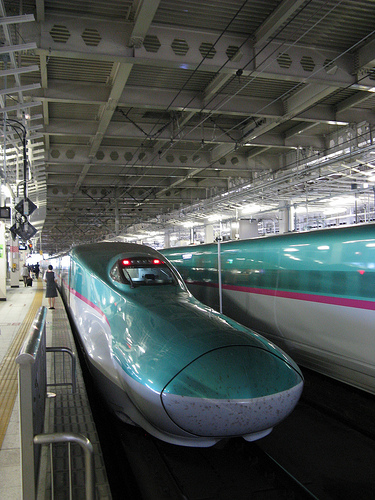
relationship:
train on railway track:
[37, 240, 305, 448] [128, 438, 296, 499]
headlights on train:
[119, 256, 165, 268] [42, 243, 315, 461]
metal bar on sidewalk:
[38, 343, 80, 408] [1, 271, 112, 499]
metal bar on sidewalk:
[30, 431, 96, 498] [1, 271, 112, 499]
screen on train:
[118, 265, 176, 286] [37, 240, 305, 448]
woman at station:
[43, 265, 58, 310] [4, 236, 374, 376]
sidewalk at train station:
[15, 262, 63, 352] [2, 0, 373, 499]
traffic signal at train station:
[25, 241, 33, 250] [2, 0, 373, 499]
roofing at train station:
[23, 16, 350, 195] [2, 0, 373, 499]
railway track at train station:
[171, 453, 294, 498] [2, 0, 373, 499]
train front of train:
[160, 341, 310, 447] [42, 243, 315, 461]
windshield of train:
[116, 259, 177, 286] [51, 235, 248, 398]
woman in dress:
[43, 265, 58, 310] [43, 269, 60, 298]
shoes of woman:
[34, 295, 82, 331] [27, 271, 73, 311]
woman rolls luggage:
[21, 264, 29, 287] [27, 277, 33, 285]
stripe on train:
[289, 282, 374, 327] [160, 212, 374, 401]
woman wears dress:
[39, 262, 64, 312] [40, 267, 60, 297]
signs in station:
[6, 169, 61, 241] [23, 35, 363, 298]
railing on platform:
[39, 342, 81, 395] [0, 276, 107, 497]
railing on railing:
[27, 427, 101, 498] [39, 342, 81, 395]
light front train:
[154, 258, 160, 264] [37, 240, 305, 448]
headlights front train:
[122, 259, 129, 265] [37, 240, 305, 448]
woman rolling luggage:
[18, 263, 36, 286] [15, 271, 35, 289]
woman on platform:
[43, 265, 58, 310] [2, 264, 89, 380]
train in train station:
[37, 240, 305, 448] [2, 0, 373, 499]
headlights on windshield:
[122, 259, 129, 265] [122, 265, 175, 284]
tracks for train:
[254, 440, 330, 497] [37, 240, 305, 448]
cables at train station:
[101, 111, 244, 176] [2, 0, 373, 499]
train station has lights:
[2, 0, 373, 499] [113, 183, 357, 241]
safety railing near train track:
[17, 307, 95, 492] [105, 428, 323, 498]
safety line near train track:
[20, 284, 47, 354] [105, 428, 323, 498]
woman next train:
[43, 265, 58, 310] [32, 213, 300, 498]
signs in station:
[9, 190, 41, 247] [224, 263, 340, 321]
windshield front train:
[122, 265, 175, 284] [37, 240, 305, 448]